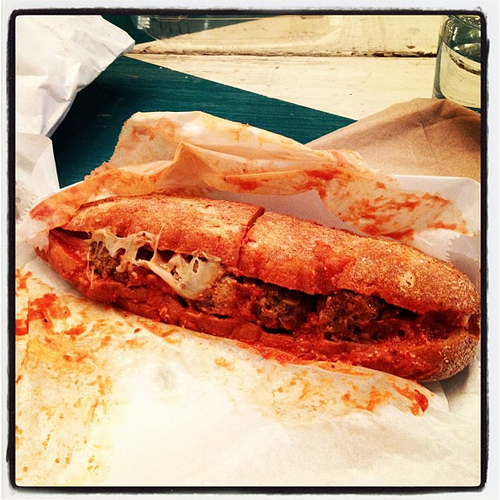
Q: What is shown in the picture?
A: A subway sandwich.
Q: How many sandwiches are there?
A: One.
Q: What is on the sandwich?
A: Meatballs.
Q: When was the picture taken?
A: At meal time.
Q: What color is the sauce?
A: Red.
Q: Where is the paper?
A: Around the sandwich.